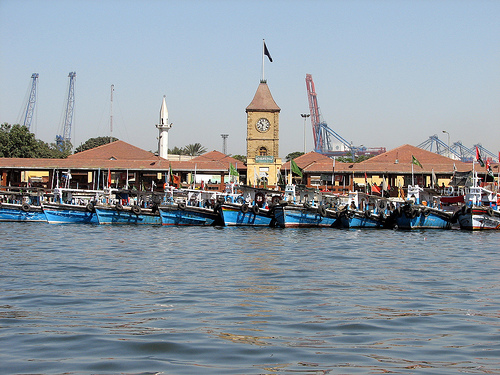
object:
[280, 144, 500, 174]
roof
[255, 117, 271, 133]
clock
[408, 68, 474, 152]
ground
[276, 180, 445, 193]
people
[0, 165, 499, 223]
dock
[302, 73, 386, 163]
crane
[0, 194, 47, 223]
boat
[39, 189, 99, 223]
boat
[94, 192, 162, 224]
boat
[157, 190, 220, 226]
boat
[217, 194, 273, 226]
boat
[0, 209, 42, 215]
stripe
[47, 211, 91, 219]
stripe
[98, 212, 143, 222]
stripe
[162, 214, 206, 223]
stripe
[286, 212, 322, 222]
stripe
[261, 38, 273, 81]
flag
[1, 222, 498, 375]
ocean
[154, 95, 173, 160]
tower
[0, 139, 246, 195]
building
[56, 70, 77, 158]
cranes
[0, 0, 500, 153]
sky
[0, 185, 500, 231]
boats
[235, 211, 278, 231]
shadow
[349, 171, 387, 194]
flag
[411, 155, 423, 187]
flag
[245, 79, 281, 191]
building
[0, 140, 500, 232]
structure